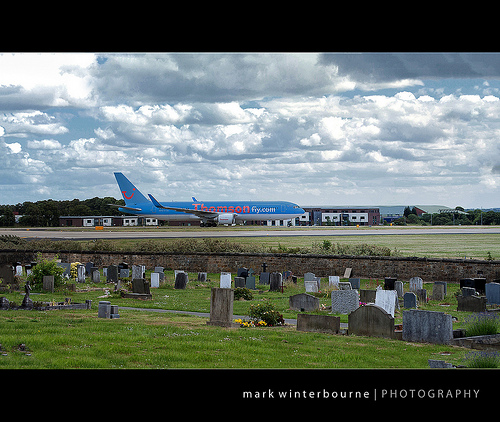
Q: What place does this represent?
A: It represents the cemetery.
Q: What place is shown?
A: It is a cemetery.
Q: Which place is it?
A: It is a cemetery.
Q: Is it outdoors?
A: Yes, it is outdoors.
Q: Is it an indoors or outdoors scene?
A: It is outdoors.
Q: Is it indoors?
A: No, it is outdoors.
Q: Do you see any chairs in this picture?
A: No, there are no chairs.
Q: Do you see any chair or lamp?
A: No, there are no chairs or lamps.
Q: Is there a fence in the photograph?
A: No, there are no fences.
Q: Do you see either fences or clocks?
A: No, there are no fences or clocks.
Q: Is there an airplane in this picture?
A: Yes, there is an airplane.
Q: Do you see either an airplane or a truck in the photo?
A: Yes, there is an airplane.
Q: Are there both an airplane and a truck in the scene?
A: No, there is an airplane but no trucks.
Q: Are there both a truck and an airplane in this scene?
A: No, there is an airplane but no trucks.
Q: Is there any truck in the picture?
A: No, there are no trucks.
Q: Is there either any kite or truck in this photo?
A: No, there are no trucks or kites.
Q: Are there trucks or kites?
A: No, there are no trucks or kites.